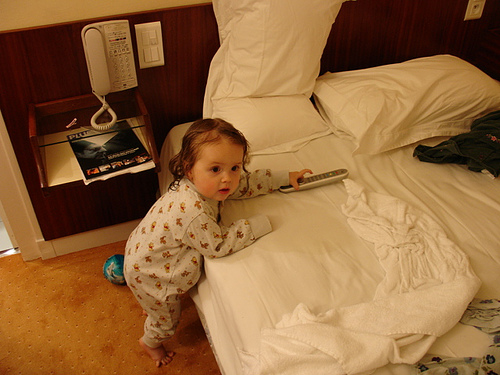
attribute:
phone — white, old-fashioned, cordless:
[81, 19, 140, 132]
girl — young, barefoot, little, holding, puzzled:
[122, 118, 315, 366]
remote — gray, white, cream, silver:
[279, 168, 350, 195]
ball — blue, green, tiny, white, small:
[103, 254, 127, 285]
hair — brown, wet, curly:
[168, 116, 250, 199]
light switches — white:
[133, 22, 165, 70]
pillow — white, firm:
[202, 3, 345, 157]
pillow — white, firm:
[310, 54, 499, 155]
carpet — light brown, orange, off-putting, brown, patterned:
[0, 238, 224, 374]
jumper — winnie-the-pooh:
[121, 169, 296, 345]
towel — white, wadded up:
[260, 179, 483, 374]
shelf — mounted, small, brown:
[28, 89, 161, 195]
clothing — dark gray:
[413, 108, 500, 177]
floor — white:
[0, 217, 11, 255]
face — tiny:
[195, 144, 244, 202]